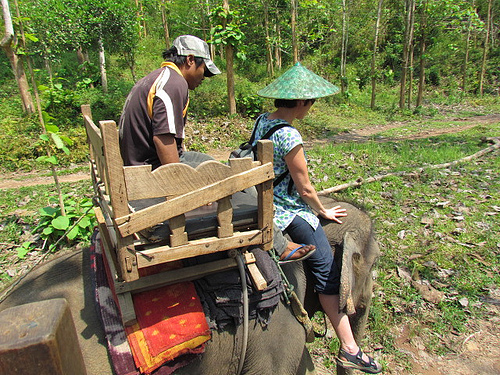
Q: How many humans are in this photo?
A: Two.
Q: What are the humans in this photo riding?
A: Elephant.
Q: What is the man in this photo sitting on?
A: Bench.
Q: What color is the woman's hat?
A: Green.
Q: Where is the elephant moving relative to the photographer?
A: Right side.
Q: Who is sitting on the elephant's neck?
A: Woman.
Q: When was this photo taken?
A: Daytime.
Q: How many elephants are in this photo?
A: One.